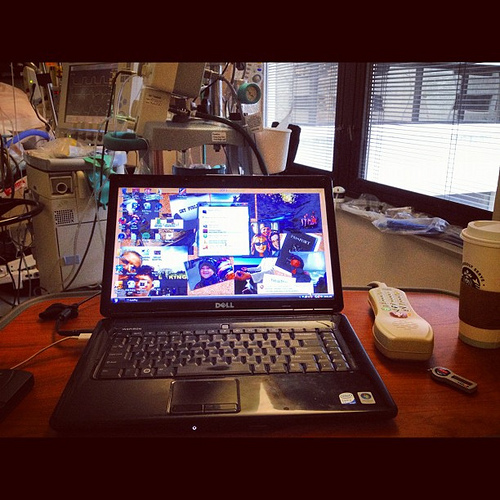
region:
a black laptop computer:
[61, 170, 381, 430]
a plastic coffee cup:
[451, 215, 496, 357]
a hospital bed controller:
[362, 270, 434, 378]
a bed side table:
[1, 284, 467, 467]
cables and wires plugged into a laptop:
[35, 285, 105, 370]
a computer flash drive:
[424, 357, 479, 403]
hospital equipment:
[0, 67, 275, 222]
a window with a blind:
[351, 87, 488, 222]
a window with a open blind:
[246, 68, 346, 167]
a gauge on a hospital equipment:
[227, 73, 277, 127]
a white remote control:
[353, 269, 439, 361]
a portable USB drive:
[423, 360, 478, 396]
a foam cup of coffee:
[445, 217, 499, 350]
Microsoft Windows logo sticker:
[356, 386, 376, 406]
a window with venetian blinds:
[357, 63, 498, 216]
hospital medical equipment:
[24, 66, 141, 281]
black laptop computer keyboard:
[97, 323, 350, 381]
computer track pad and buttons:
[161, 377, 241, 416]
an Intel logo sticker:
[335, 391, 357, 407]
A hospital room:
[15, 12, 495, 477]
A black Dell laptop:
[57, 174, 392, 426]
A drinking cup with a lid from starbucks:
[451, 218, 497, 348]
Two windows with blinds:
[266, 62, 496, 217]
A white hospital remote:
[365, 280, 437, 370]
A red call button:
[387, 309, 412, 323]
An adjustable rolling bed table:
[0, 270, 492, 475]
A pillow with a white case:
[0, 82, 45, 137]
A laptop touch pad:
[153, 374, 260, 439]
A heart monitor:
[61, 64, 141, 147]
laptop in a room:
[10, 65, 495, 460]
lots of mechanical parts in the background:
[15, 60, 396, 316]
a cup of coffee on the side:
[433, 197, 499, 357]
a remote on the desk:
[351, 267, 478, 398]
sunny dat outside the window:
[266, 63, 498, 236]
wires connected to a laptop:
[16, 263, 114, 426]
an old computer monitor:
[42, 59, 157, 151]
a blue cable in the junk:
[6, 124, 118, 181]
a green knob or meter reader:
[213, 73, 295, 120]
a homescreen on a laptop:
[96, 173, 363, 306]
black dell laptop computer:
[45, 172, 399, 433]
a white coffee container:
[456, 219, 498, 348]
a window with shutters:
[251, 56, 498, 234]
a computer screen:
[110, 183, 335, 300]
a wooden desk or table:
[409, 399, 473, 424]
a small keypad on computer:
[165, 377, 243, 417]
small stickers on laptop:
[330, 384, 380, 406]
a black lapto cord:
[50, 283, 100, 335]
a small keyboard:
[93, 327, 351, 379]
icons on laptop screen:
[115, 187, 167, 299]